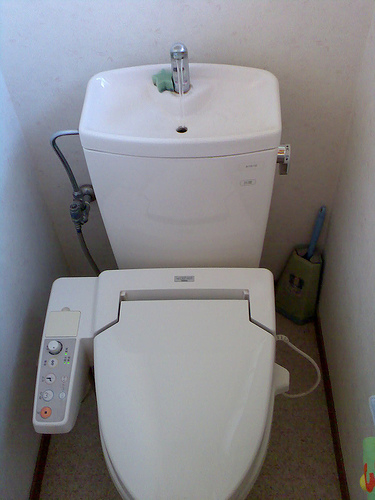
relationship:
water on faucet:
[174, 59, 186, 131] [169, 43, 190, 93]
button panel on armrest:
[36, 339, 76, 423] [25, 271, 97, 436]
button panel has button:
[36, 339, 76, 423] [45, 338, 64, 354]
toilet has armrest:
[30, 43, 322, 500] [25, 271, 97, 436]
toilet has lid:
[28, 37, 325, 497] [74, 40, 285, 162]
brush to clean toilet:
[303, 204, 330, 261] [84, 250, 289, 499]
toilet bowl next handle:
[72, 57, 286, 260] [301, 200, 331, 259]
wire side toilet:
[273, 332, 322, 398] [30, 43, 322, 500]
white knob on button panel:
[45, 337, 63, 355] [30, 332, 75, 427]